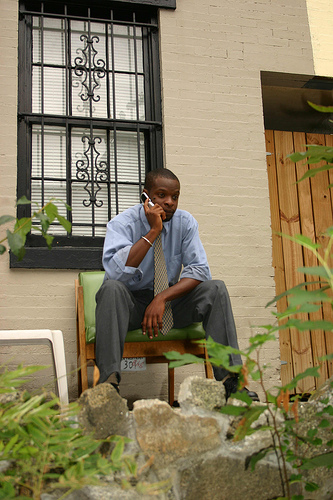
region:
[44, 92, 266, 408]
Man talking on cell phone.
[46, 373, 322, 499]
A rock formation.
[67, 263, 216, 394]
A wooden chair.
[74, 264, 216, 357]
Green cushions on chair.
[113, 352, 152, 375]
White sign attached to chair.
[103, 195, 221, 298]
Blue long sleeve shirt.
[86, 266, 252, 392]
Grey dress pants.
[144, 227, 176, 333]
A dark tie with design.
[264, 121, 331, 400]
A wood door with vertical boards.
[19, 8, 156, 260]
Black grill work over window.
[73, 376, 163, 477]
The rocks are visible.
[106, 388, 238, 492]
The rocks are visible.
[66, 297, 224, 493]
The rocks are visible.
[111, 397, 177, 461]
The rocks are visible.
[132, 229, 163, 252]
small silver bracelet on man's hand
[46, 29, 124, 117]
black iron grate design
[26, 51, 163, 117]
white blinds in window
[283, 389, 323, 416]
black bracket on brown door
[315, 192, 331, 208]
tiny hole in brown door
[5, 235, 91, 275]
black window sill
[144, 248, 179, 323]
large multi colored tie around man's neck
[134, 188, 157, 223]
black and tan cell phone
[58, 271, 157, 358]
large green and brown chair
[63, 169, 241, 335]
man sitting on chair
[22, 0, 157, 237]
black grate on window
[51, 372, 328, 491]
wall made of rocks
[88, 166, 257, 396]
well dressed man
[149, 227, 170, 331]
yellow patterned tie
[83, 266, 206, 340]
green chair cushion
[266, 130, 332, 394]
wooden fence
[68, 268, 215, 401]
wooden chair with green cushion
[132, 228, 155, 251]
silver bracelet on right wrist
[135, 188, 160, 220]
silver and black flip phone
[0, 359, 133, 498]
green leafy plants in front of wall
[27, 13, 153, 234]
window has bars on it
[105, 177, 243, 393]
man is sitting in a chair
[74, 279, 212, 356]
the chair is lime green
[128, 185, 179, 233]
man is talking on a cellphone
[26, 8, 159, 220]
the metal bars are black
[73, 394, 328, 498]
rock wall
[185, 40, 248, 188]
the bricks are white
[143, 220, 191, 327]
man is wearing a tie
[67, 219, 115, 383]
chair is under the window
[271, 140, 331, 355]
door is made of wood